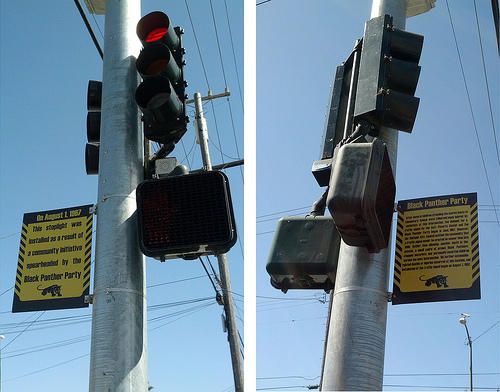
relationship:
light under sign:
[457, 313, 469, 325] [394, 190, 484, 305]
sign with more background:
[394, 190, 484, 305] [390, 191, 481, 307]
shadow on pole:
[98, 68, 137, 384] [88, 0, 149, 389]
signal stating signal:
[135, 167, 235, 259] [135, 170, 238, 261]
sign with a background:
[10, 204, 92, 312] [17, 217, 86, 305]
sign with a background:
[394, 190, 484, 305] [400, 206, 474, 290]